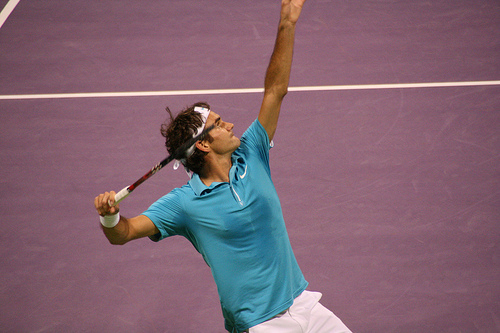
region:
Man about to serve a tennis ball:
[67, 50, 417, 330]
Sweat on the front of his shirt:
[205, 208, 291, 272]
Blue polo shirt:
[145, 170, 338, 328]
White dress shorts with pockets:
[227, 305, 362, 330]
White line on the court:
[362, 64, 499, 196]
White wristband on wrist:
[89, 206, 125, 239]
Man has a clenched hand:
[92, 182, 141, 234]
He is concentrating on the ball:
[178, 84, 263, 160]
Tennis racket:
[90, 117, 235, 217]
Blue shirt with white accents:
[185, 172, 287, 247]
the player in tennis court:
[87, 47, 392, 319]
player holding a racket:
[42, 93, 317, 274]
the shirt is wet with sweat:
[142, 137, 325, 328]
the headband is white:
[108, 72, 242, 195]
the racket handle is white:
[74, 111, 309, 261]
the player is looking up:
[64, 23, 359, 330]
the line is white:
[27, 64, 194, 136]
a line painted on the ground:
[27, 64, 194, 114]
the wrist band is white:
[77, 177, 152, 244]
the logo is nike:
[172, 137, 293, 274]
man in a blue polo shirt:
[72, 83, 327, 332]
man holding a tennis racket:
[86, 75, 353, 306]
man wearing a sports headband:
[43, 44, 444, 331]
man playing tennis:
[52, 20, 355, 320]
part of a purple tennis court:
[8, 32, 98, 298]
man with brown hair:
[61, 53, 417, 328]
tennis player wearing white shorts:
[71, 60, 363, 331]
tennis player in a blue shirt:
[59, 12, 364, 327]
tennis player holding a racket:
[74, 74, 464, 326]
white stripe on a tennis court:
[9, 70, 127, 135]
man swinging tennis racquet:
[93, 0, 353, 328]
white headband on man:
[170, 105, 205, 175]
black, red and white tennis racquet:
[105, 120, 216, 205]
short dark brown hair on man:
[156, 100, 208, 177]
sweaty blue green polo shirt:
[141, 117, 306, 327]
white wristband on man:
[96, 210, 116, 225]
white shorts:
[230, 285, 350, 330]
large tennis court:
[0, 0, 496, 330]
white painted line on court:
[0, 75, 499, 95]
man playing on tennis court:
[93, 0, 353, 331]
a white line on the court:
[8, 58, 239, 100]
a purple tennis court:
[3, 65, 487, 326]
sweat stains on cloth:
[209, 185, 290, 277]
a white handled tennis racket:
[98, 118, 237, 212]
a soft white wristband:
[94, 210, 130, 235]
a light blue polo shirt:
[117, 110, 342, 327]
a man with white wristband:
[153, 92, 250, 192]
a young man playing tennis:
[78, 20, 408, 330]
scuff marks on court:
[348, 85, 498, 192]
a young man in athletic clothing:
[51, 73, 354, 331]